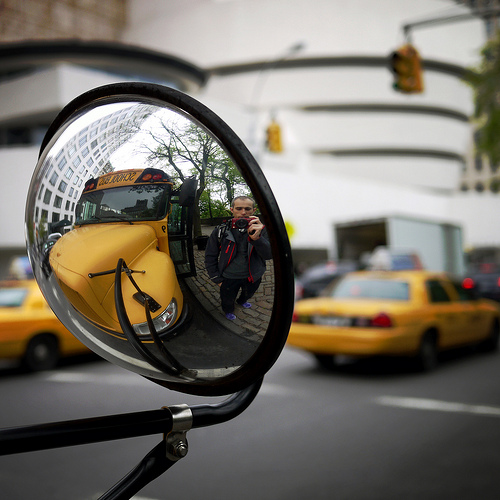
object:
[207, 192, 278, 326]
man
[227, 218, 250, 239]
camera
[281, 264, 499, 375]
taxi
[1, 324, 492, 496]
street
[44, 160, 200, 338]
bus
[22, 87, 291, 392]
mirror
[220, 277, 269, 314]
pants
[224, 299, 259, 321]
sneakers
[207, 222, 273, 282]
jacket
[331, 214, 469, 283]
truck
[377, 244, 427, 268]
ad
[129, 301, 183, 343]
headlights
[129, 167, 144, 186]
letter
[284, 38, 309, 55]
light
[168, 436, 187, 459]
bolt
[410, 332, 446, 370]
back tire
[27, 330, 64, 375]
tire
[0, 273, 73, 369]
cab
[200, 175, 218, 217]
leaves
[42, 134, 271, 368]
reflection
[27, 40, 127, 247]
building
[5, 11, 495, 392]
background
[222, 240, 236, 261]
trim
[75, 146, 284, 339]
photo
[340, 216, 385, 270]
door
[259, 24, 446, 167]
lights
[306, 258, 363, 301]
van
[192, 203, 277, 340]
sidewalk